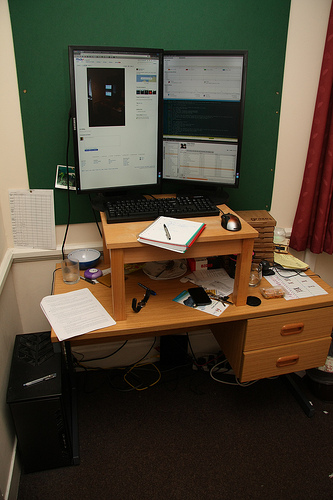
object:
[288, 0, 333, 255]
curtain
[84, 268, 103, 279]
inhaler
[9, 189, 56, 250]
paper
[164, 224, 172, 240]
pen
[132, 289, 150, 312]
black watch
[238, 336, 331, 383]
drawer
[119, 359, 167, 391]
cord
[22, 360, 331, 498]
ground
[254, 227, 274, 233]
box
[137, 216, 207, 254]
notebook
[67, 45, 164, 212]
computer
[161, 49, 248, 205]
computer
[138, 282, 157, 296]
pen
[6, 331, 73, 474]
processor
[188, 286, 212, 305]
cellphone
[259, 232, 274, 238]
box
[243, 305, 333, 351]
drawer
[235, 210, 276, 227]
box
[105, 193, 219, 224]
keyboard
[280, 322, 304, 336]
drawer pull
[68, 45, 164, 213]
display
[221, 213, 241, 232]
mouse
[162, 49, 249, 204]
monitor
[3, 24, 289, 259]
wall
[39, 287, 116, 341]
papers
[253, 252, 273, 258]
cd rack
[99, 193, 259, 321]
desk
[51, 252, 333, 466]
desk